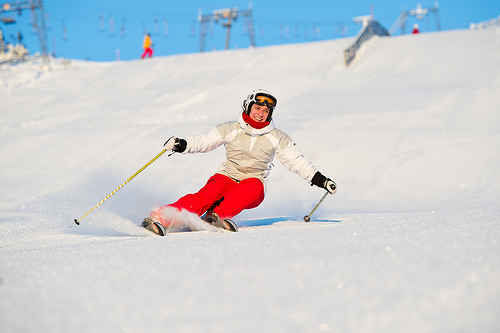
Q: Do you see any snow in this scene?
A: Yes, there is snow.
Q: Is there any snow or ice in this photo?
A: Yes, there is snow.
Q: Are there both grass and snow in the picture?
A: No, there is snow but no grass.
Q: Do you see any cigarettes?
A: No, there are no cigarettes.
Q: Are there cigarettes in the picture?
A: No, there are no cigarettes.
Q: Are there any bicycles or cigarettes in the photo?
A: No, there are no cigarettes or bicycles.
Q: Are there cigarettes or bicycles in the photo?
A: No, there are no cigarettes or bicycles.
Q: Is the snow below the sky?
A: Yes, the snow is below the sky.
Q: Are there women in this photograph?
A: Yes, there is a woman.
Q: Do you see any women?
A: Yes, there is a woman.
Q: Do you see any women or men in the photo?
A: Yes, there is a woman.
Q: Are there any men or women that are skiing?
A: Yes, the woman is skiing.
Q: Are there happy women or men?
A: Yes, there is a happy woman.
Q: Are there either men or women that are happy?
A: Yes, the woman is happy.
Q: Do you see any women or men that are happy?
A: Yes, the woman is happy.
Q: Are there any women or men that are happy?
A: Yes, the woman is happy.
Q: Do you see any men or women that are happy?
A: Yes, the woman is happy.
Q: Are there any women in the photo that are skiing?
A: Yes, there is a woman that is skiing.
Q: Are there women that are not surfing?
A: Yes, there is a woman that is skiing.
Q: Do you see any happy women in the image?
A: Yes, there is a happy woman.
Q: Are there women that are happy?
A: Yes, there is a woman that is happy.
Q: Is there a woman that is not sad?
A: Yes, there is a happy woman.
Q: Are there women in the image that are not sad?
A: Yes, there is a happy woman.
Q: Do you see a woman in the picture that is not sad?
A: Yes, there is a happy woman.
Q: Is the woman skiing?
A: Yes, the woman is skiing.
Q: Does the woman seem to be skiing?
A: Yes, the woman is skiing.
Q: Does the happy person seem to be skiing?
A: Yes, the woman is skiing.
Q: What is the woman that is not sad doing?
A: The woman is skiing.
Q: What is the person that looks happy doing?
A: The woman is skiing.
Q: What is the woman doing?
A: The woman is skiing.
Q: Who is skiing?
A: The woman is skiing.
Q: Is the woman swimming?
A: No, the woman is skiing.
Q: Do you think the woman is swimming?
A: No, the woman is skiing.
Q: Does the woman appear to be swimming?
A: No, the woman is skiing.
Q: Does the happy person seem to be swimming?
A: No, the woman is skiing.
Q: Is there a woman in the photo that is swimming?
A: No, there is a woman but she is skiing.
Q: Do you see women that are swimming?
A: No, there is a woman but she is skiing.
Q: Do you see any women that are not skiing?
A: No, there is a woman but she is skiing.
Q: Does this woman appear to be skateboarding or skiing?
A: The woman is skiing.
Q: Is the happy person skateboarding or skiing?
A: The woman is skiing.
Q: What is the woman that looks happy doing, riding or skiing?
A: The woman is skiing.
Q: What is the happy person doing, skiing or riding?
A: The woman is skiing.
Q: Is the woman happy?
A: Yes, the woman is happy.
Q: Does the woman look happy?
A: Yes, the woman is happy.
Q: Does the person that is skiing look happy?
A: Yes, the woman is happy.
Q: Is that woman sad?
A: No, the woman is happy.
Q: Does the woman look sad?
A: No, the woman is happy.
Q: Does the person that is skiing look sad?
A: No, the woman is happy.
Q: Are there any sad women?
A: No, there is a woman but she is happy.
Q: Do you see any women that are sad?
A: No, there is a woman but she is happy.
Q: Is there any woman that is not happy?
A: No, there is a woman but she is happy.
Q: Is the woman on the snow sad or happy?
A: The woman is happy.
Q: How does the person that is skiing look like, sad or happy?
A: The woman is happy.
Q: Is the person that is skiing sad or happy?
A: The woman is happy.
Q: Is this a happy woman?
A: Yes, this is a happy woman.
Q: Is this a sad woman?
A: No, this is a happy woman.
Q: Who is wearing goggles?
A: The woman is wearing goggles.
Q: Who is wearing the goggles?
A: The woman is wearing goggles.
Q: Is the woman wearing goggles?
A: Yes, the woman is wearing goggles.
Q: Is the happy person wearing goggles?
A: Yes, the woman is wearing goggles.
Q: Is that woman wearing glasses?
A: No, the woman is wearing goggles.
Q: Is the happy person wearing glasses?
A: No, the woman is wearing goggles.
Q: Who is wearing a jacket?
A: The woman is wearing a jacket.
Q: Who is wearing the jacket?
A: The woman is wearing a jacket.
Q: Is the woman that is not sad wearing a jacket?
A: Yes, the woman is wearing a jacket.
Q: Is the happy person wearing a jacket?
A: Yes, the woman is wearing a jacket.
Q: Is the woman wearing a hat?
A: No, the woman is wearing a jacket.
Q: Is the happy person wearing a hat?
A: No, the woman is wearing a jacket.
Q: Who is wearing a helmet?
A: The woman is wearing a helmet.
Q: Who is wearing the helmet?
A: The woman is wearing a helmet.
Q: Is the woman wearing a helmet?
A: Yes, the woman is wearing a helmet.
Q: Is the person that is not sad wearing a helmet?
A: Yes, the woman is wearing a helmet.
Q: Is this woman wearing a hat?
A: No, the woman is wearing a helmet.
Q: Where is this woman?
A: The woman is on the snow.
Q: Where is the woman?
A: The woman is on the snow.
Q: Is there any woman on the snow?
A: Yes, there is a woman on the snow.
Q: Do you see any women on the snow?
A: Yes, there is a woman on the snow.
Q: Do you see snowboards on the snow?
A: No, there is a woman on the snow.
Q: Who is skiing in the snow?
A: The woman is skiing in the snow.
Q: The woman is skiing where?
A: The woman is skiing in the snow.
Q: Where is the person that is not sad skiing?
A: The woman is skiing in the snow.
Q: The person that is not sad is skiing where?
A: The woman is skiing in the snow.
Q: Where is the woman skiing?
A: The woman is skiing in the snow.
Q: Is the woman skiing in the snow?
A: Yes, the woman is skiing in the snow.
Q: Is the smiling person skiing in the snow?
A: Yes, the woman is skiing in the snow.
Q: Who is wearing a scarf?
A: The woman is wearing a scarf.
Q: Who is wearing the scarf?
A: The woman is wearing a scarf.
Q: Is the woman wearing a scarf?
A: Yes, the woman is wearing a scarf.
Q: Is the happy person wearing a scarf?
A: Yes, the woman is wearing a scarf.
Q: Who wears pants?
A: The woman wears pants.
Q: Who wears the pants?
A: The woman wears pants.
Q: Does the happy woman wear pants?
A: Yes, the woman wears pants.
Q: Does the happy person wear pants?
A: Yes, the woman wears pants.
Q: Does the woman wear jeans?
A: No, the woman wears pants.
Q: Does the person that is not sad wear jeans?
A: No, the woman wears pants.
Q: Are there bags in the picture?
A: No, there are no bags.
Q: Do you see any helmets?
A: Yes, there is a helmet.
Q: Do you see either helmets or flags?
A: Yes, there is a helmet.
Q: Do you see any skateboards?
A: No, there are no skateboards.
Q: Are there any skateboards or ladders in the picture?
A: No, there are no skateboards or ladders.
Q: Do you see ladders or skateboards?
A: No, there are no skateboards or ladders.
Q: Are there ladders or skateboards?
A: No, there are no skateboards or ladders.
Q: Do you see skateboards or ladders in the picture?
A: No, there are no skateboards or ladders.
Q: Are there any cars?
A: No, there are no cars.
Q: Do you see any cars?
A: No, there are no cars.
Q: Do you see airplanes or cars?
A: No, there are no cars or airplanes.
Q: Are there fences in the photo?
A: Yes, there is a fence.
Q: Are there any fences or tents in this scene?
A: Yes, there is a fence.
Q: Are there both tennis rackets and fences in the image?
A: No, there is a fence but no rackets.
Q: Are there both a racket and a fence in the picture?
A: No, there is a fence but no rackets.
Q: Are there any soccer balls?
A: No, there are no soccer balls.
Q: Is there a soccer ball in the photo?
A: No, there are no soccer balls.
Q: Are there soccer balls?
A: No, there are no soccer balls.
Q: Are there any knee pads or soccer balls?
A: No, there are no soccer balls or knee pads.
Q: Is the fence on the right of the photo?
A: Yes, the fence is on the right of the image.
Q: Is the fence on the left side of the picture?
A: No, the fence is on the right of the image.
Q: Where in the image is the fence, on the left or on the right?
A: The fence is on the right of the image.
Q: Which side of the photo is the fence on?
A: The fence is on the right of the image.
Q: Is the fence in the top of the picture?
A: Yes, the fence is in the top of the image.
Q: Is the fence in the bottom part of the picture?
A: No, the fence is in the top of the image.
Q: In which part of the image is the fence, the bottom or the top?
A: The fence is in the top of the image.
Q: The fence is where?
A: The fence is on the snow.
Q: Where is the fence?
A: The fence is on the snow.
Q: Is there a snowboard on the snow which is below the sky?
A: No, there is a fence on the snow.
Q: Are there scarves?
A: Yes, there is a scarf.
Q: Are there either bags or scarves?
A: Yes, there is a scarf.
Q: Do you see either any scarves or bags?
A: Yes, there is a scarf.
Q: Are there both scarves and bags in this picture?
A: No, there is a scarf but no bags.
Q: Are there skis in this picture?
A: Yes, there are skis.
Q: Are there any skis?
A: Yes, there are skis.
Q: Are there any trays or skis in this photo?
A: Yes, there are skis.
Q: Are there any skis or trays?
A: Yes, there are skis.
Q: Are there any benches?
A: No, there are no benches.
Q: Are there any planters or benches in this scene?
A: No, there are no benches or planters.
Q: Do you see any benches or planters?
A: No, there are no benches or planters.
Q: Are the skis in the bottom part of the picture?
A: Yes, the skis are in the bottom of the image.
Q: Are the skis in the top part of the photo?
A: No, the skis are in the bottom of the image.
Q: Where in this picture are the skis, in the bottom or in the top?
A: The skis are in the bottom of the image.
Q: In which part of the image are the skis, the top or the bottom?
A: The skis are in the bottom of the image.